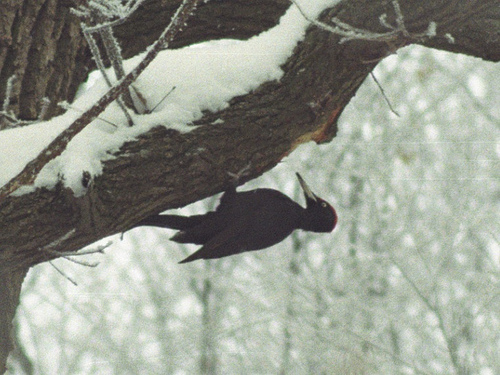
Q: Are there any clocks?
A: No, there are no clocks.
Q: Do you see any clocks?
A: No, there are no clocks.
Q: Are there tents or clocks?
A: No, there are no clocks or tents.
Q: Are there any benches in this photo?
A: No, there are no benches.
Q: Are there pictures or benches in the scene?
A: No, there are no benches or pictures.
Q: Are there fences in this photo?
A: No, there are no fences.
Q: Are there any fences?
A: No, there are no fences.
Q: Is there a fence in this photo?
A: No, there are no fences.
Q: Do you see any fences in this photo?
A: No, there are no fences.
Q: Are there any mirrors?
A: No, there are no mirrors.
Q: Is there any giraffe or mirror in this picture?
A: No, there are no mirrors or giraffes.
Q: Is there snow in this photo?
A: Yes, there is snow.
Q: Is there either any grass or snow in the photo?
A: Yes, there is snow.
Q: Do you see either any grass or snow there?
A: Yes, there is snow.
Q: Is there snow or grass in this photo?
A: Yes, there is snow.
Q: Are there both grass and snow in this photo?
A: No, there is snow but no grass.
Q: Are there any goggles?
A: No, there are no goggles.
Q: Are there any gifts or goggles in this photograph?
A: No, there are no goggles or gifts.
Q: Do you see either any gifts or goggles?
A: No, there are no goggles or gifts.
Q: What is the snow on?
A: The snow is on the branch.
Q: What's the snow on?
A: The snow is on the branch.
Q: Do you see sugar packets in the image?
A: No, there are no sugar packets.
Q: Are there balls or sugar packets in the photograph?
A: No, there are no sugar packets or balls.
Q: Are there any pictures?
A: No, there are no pictures.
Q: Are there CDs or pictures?
A: No, there are no pictures or cds.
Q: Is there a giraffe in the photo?
A: No, there are no giraffes.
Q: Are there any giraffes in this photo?
A: No, there are no giraffes.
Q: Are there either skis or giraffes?
A: No, there are no giraffes or skis.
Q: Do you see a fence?
A: No, there are no fences.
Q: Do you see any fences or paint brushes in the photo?
A: No, there are no fences or paint brushes.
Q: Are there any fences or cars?
A: No, there are no fences or cars.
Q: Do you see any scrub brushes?
A: No, there are no scrub brushes.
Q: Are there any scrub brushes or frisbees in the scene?
A: No, there are no scrub brushes or frisbees.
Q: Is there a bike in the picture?
A: No, there are no bikes.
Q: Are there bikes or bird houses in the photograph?
A: No, there are no bikes or bird houses.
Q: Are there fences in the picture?
A: No, there are no fences.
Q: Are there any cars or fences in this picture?
A: No, there are no fences or cars.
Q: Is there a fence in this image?
A: No, there are no fences.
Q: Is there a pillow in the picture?
A: No, there are no pillows.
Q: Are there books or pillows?
A: No, there are no pillows or books.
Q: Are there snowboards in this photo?
A: No, there are no snowboards.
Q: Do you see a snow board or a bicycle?
A: No, there are no snowboards or bicycles.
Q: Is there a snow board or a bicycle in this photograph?
A: No, there are no snowboards or bicycles.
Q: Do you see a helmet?
A: No, there are no helmets.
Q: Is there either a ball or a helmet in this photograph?
A: No, there are no helmets or balls.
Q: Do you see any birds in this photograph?
A: Yes, there is a bird.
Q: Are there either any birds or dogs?
A: Yes, there is a bird.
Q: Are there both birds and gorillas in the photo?
A: No, there is a bird but no gorillas.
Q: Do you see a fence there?
A: No, there are no fences.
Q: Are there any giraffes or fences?
A: No, there are no fences or giraffes.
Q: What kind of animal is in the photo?
A: The animal is a bird.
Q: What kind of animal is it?
A: The animal is a bird.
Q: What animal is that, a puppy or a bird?
A: That is a bird.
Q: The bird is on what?
A: The bird is on the branch.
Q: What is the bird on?
A: The bird is on the branch.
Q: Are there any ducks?
A: No, there are no ducks.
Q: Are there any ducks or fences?
A: No, there are no ducks or fences.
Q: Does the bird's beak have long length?
A: Yes, the beak is long.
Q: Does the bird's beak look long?
A: Yes, the beak is long.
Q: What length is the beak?
A: The beak is long.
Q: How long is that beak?
A: The beak is long.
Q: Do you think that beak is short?
A: No, the beak is long.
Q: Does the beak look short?
A: No, the beak is long.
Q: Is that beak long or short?
A: The beak is long.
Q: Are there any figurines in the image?
A: No, there are no figurines.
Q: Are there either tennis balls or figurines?
A: No, there are no figurines or tennis balls.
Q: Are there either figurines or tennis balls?
A: No, there are no figurines or tennis balls.